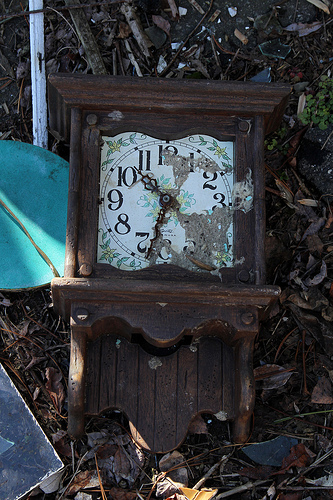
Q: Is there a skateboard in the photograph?
A: No, there are no skateboards.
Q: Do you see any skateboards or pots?
A: No, there are no skateboards or pots.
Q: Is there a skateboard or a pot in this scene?
A: No, there are no skateboards or pots.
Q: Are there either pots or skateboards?
A: No, there are no skateboards or pots.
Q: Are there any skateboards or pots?
A: No, there are no skateboards or pots.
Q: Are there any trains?
A: No, there are no trains.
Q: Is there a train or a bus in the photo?
A: No, there are no trains or buses.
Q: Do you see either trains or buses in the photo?
A: No, there are no trains or buses.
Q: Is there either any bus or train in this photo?
A: No, there are no trains or buses.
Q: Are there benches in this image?
A: No, there are no benches.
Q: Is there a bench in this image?
A: No, there are no benches.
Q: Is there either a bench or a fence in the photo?
A: No, there are no benches or fences.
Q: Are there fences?
A: No, there are no fences.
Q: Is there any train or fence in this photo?
A: No, there are no fences or trains.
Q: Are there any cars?
A: No, there are no cars.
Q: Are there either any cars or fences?
A: No, there are no cars or fences.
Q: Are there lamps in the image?
A: No, there are no lamps.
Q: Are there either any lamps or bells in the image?
A: No, there are no lamps or bells.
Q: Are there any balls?
A: No, there are no balls.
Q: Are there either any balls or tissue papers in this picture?
A: No, there are no balls or tissue papers.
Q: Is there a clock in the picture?
A: Yes, there is a clock.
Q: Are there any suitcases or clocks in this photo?
A: Yes, there is a clock.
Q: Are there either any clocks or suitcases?
A: Yes, there is a clock.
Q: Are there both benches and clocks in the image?
A: No, there is a clock but no benches.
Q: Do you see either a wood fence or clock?
A: Yes, there is a wood clock.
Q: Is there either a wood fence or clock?
A: Yes, there is a wood clock.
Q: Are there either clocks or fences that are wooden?
A: Yes, the clock is wooden.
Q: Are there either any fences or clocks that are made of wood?
A: Yes, the clock is made of wood.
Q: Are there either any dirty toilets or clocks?
A: Yes, there is a dirty clock.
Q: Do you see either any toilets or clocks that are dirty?
A: Yes, the clock is dirty.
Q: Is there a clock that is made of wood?
A: Yes, there is a clock that is made of wood.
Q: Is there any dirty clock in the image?
A: Yes, there is a dirty clock.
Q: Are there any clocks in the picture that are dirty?
A: Yes, there is a clock that is dirty.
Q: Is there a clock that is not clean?
A: Yes, there is a dirty clock.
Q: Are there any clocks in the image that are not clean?
A: Yes, there is a dirty clock.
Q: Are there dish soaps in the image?
A: No, there are no dish soaps.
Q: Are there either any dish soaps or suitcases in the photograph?
A: No, there are no dish soaps or suitcases.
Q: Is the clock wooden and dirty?
A: Yes, the clock is wooden and dirty.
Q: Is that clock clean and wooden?
A: No, the clock is wooden but dirty.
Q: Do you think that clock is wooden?
A: Yes, the clock is wooden.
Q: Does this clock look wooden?
A: Yes, the clock is wooden.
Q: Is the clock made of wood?
A: Yes, the clock is made of wood.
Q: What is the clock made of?
A: The clock is made of wood.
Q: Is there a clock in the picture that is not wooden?
A: No, there is a clock but it is wooden.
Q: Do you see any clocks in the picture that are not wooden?
A: No, there is a clock but it is wooden.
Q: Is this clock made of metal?
A: No, the clock is made of wood.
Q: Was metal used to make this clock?
A: No, the clock is made of wood.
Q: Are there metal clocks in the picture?
A: No, there is a clock but it is made of wood.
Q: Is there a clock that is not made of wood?
A: No, there is a clock but it is made of wood.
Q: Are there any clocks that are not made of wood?
A: No, there is a clock but it is made of wood.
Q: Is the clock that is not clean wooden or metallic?
A: The clock is wooden.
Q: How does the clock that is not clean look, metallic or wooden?
A: The clock is wooden.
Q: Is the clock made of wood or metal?
A: The clock is made of wood.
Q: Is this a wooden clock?
A: Yes, this is a wooden clock.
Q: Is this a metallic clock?
A: No, this is a wooden clock.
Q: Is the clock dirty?
A: Yes, the clock is dirty.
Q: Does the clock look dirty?
A: Yes, the clock is dirty.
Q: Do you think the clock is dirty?
A: Yes, the clock is dirty.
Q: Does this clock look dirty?
A: Yes, the clock is dirty.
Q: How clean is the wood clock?
A: The clock is dirty.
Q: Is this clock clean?
A: No, the clock is dirty.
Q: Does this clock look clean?
A: No, the clock is dirty.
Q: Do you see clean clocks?
A: No, there is a clock but it is dirty.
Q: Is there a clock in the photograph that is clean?
A: No, there is a clock but it is dirty.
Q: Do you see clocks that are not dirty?
A: No, there is a clock but it is dirty.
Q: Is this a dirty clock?
A: Yes, this is a dirty clock.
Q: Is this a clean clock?
A: No, this is a dirty clock.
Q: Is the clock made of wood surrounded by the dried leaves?
A: Yes, the clock is surrounded by the leaves.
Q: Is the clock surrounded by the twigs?
A: Yes, the clock is surrounded by the twigs.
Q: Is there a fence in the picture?
A: No, there are no fences.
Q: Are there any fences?
A: No, there are no fences.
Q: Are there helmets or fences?
A: No, there are no fences or helmets.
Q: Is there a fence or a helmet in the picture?
A: No, there are no fences or helmets.